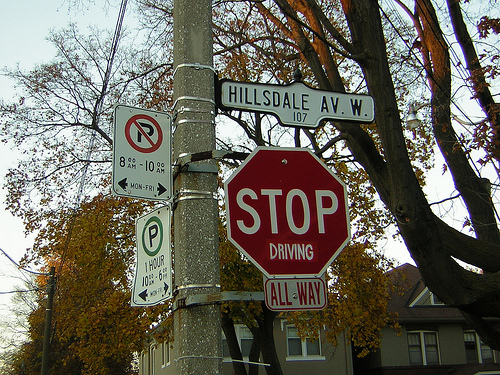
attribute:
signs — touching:
[106, 75, 376, 313]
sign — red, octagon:
[226, 145, 353, 278]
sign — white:
[212, 72, 379, 129]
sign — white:
[114, 103, 175, 203]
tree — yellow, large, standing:
[30, 189, 170, 375]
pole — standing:
[43, 261, 60, 375]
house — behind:
[355, 263, 497, 369]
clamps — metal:
[160, 55, 235, 313]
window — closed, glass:
[401, 330, 450, 370]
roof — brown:
[382, 262, 478, 323]